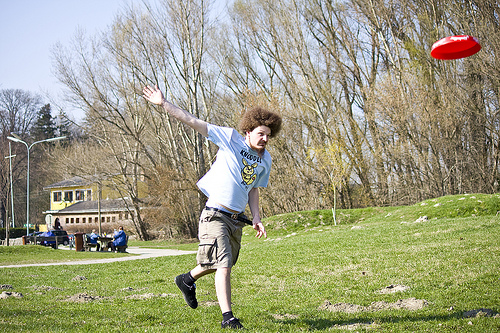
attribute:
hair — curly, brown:
[226, 107, 325, 159]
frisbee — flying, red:
[430, 35, 493, 73]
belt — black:
[204, 205, 274, 241]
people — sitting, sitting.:
[84, 224, 137, 247]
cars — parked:
[50, 221, 137, 253]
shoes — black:
[166, 265, 245, 330]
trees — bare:
[143, 30, 291, 118]